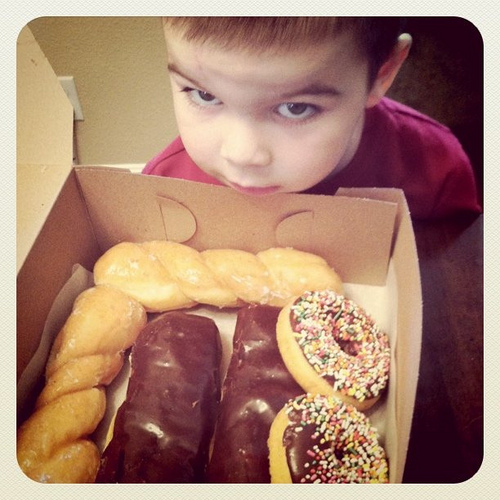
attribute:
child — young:
[126, 18, 478, 261]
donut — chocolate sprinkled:
[267, 281, 393, 403]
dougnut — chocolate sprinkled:
[260, 393, 394, 486]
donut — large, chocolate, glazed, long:
[103, 304, 229, 485]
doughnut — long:
[212, 293, 282, 479]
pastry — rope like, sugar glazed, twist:
[90, 236, 347, 315]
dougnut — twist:
[19, 281, 152, 483]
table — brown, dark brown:
[419, 206, 481, 474]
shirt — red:
[135, 101, 482, 223]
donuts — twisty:
[30, 239, 399, 500]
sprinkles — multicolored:
[289, 287, 406, 391]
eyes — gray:
[176, 84, 324, 123]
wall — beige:
[74, 19, 164, 150]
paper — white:
[37, 248, 85, 334]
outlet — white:
[55, 70, 87, 127]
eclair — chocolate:
[214, 301, 304, 483]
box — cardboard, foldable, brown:
[14, 163, 419, 483]